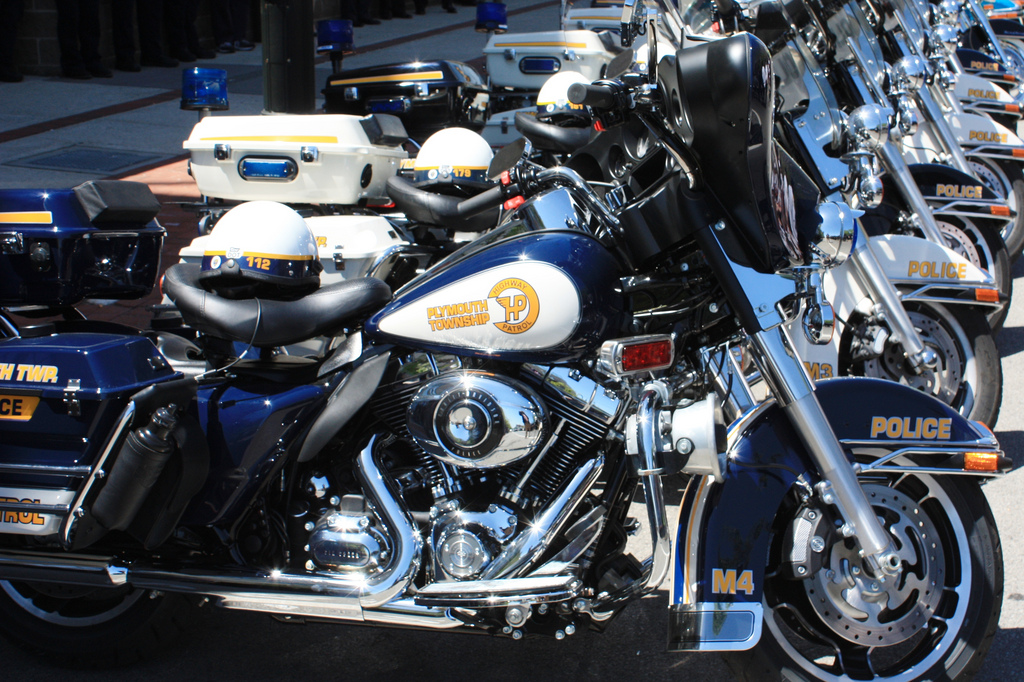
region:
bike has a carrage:
[186, 107, 405, 209]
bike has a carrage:
[1, 191, 163, 300]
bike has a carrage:
[327, 62, 490, 129]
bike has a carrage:
[484, 30, 615, 85]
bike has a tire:
[727, 454, 1004, 680]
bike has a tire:
[879, 201, 1010, 332]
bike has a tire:
[937, 147, 1021, 275]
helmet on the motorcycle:
[395, 110, 497, 191]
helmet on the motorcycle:
[534, 60, 601, 125]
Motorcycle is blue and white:
[123, 76, 1022, 661]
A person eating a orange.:
[726, 388, 851, 522]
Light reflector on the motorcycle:
[603, 331, 674, 376]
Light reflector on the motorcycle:
[954, 448, 1003, 474]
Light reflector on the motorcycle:
[964, 279, 1006, 300]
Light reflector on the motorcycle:
[983, 200, 1015, 226]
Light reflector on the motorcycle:
[1014, 142, 1022, 165]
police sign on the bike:
[856, 411, 961, 446]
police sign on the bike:
[901, 256, 971, 277]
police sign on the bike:
[925, 174, 990, 203]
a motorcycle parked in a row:
[755, 186, 949, 453]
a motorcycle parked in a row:
[847, 97, 997, 215]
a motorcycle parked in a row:
[827, 88, 1023, 289]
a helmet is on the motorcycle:
[196, 197, 326, 297]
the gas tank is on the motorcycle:
[367, 224, 614, 376]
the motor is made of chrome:
[337, 347, 629, 624]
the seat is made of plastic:
[154, 259, 385, 351]